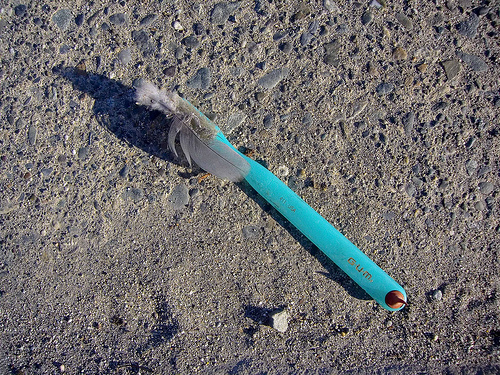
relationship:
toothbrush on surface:
[141, 21, 408, 310] [277, 67, 368, 128]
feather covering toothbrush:
[191, 155, 262, 176] [141, 21, 408, 310]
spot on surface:
[267, 73, 285, 88] [277, 67, 368, 128]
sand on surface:
[66, 55, 103, 74] [277, 67, 368, 128]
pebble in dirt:
[18, 12, 94, 43] [253, 19, 287, 36]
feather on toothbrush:
[191, 155, 262, 176] [141, 21, 408, 310]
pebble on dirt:
[18, 12, 94, 43] [253, 19, 287, 36]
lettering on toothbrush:
[337, 245, 379, 284] [141, 21, 408, 310]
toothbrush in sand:
[141, 21, 408, 310] [66, 55, 103, 74]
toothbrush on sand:
[141, 21, 408, 310] [66, 55, 103, 74]